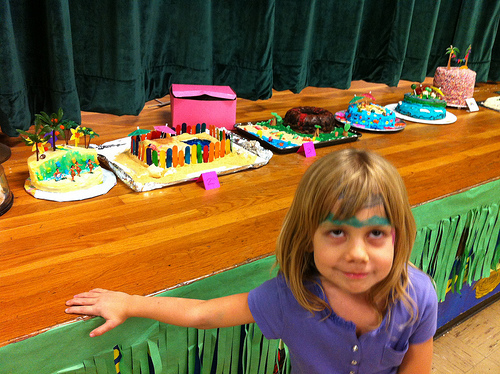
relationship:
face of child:
[304, 202, 409, 303] [70, 152, 442, 372]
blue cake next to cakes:
[401, 80, 452, 124] [434, 45, 477, 105]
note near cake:
[198, 170, 222, 190] [99, 127, 269, 193]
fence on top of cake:
[132, 121, 232, 166] [113, 123, 258, 185]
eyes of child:
[316, 218, 386, 244] [70, 152, 442, 372]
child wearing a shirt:
[66, 146, 437, 373] [237, 263, 438, 366]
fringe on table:
[8, 170, 498, 371] [1, 57, 499, 371]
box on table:
[171, 83, 239, 134] [1, 57, 499, 371]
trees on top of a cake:
[21, 104, 79, 151] [28, 135, 111, 204]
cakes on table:
[438, 41, 478, 106] [1, 57, 499, 371]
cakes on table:
[388, 82, 458, 123] [1, 57, 499, 371]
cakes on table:
[336, 90, 410, 130] [1, 57, 499, 371]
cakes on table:
[235, 106, 363, 148] [1, 57, 499, 371]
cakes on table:
[98, 124, 270, 195] [1, 57, 499, 371]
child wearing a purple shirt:
[70, 152, 442, 372] [248, 263, 439, 374]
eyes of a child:
[327, 227, 350, 237] [66, 146, 437, 373]